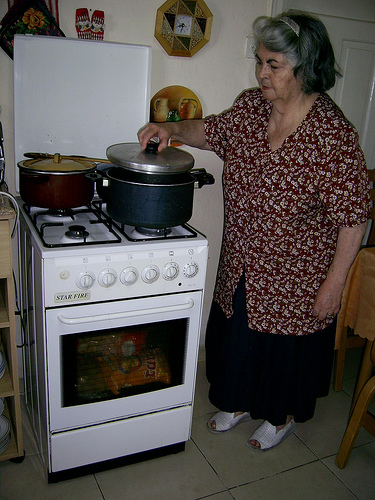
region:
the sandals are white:
[208, 409, 300, 450]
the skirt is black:
[203, 307, 356, 414]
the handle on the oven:
[58, 302, 193, 324]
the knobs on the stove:
[76, 268, 194, 283]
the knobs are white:
[74, 268, 202, 281]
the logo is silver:
[54, 288, 87, 302]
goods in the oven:
[73, 335, 171, 395]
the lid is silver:
[111, 146, 185, 174]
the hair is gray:
[267, 9, 335, 96]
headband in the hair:
[277, 13, 323, 82]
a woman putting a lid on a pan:
[88, 9, 371, 452]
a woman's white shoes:
[206, 411, 302, 451]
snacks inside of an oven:
[79, 331, 178, 394]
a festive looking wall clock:
[151, 0, 216, 60]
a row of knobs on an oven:
[78, 262, 200, 287]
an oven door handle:
[53, 298, 193, 326]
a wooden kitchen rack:
[2, 191, 30, 470]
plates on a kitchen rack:
[2, 400, 13, 460]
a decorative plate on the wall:
[150, 84, 203, 146]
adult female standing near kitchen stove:
[135, 5, 371, 451]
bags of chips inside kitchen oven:
[65, 325, 178, 407]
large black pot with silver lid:
[86, 133, 214, 235]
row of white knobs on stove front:
[73, 256, 200, 292]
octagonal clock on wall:
[150, 1, 217, 59]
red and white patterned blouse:
[197, 84, 372, 338]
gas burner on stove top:
[61, 223, 91, 243]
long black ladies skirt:
[200, 249, 337, 432]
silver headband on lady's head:
[270, 9, 305, 40]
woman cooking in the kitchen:
[137, 8, 373, 453]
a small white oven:
[15, 176, 210, 484]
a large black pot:
[83, 164, 215, 227]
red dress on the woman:
[203, 85, 371, 337]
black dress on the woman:
[204, 263, 336, 424]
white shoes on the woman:
[207, 408, 299, 449]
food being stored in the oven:
[69, 324, 172, 396]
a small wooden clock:
[154, 0, 214, 57]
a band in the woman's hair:
[274, 13, 300, 38]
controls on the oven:
[73, 260, 198, 290]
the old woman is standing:
[137, 6, 370, 452]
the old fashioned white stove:
[10, 32, 208, 483]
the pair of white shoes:
[206, 410, 297, 453]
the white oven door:
[45, 290, 201, 429]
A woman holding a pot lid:
[100, 3, 347, 183]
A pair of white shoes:
[200, 395, 296, 455]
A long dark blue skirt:
[197, 270, 338, 426]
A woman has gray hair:
[240, 3, 347, 108]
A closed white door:
[270, 0, 370, 169]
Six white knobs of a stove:
[68, 255, 203, 293]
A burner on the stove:
[26, 197, 121, 249]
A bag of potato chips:
[86, 333, 172, 396]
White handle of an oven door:
[50, 286, 197, 331]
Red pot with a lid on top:
[11, 140, 105, 221]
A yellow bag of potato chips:
[90, 332, 175, 397]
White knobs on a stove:
[70, 249, 200, 294]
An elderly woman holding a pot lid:
[97, 3, 353, 178]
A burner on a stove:
[27, 203, 125, 250]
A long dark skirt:
[195, 271, 339, 426]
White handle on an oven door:
[53, 291, 196, 327]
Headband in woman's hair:
[265, 7, 307, 43]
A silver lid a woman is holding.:
[105, 139, 193, 176]